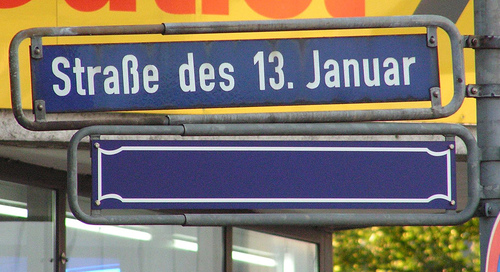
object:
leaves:
[367, 230, 393, 245]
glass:
[0, 174, 57, 271]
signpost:
[7, 22, 483, 244]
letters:
[393, 52, 416, 90]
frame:
[66, 121, 480, 224]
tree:
[329, 217, 483, 272]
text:
[52, 53, 161, 97]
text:
[52, 50, 415, 97]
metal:
[65, 125, 80, 217]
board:
[93, 139, 456, 211]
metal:
[308, 210, 344, 226]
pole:
[470, 2, 499, 269]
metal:
[41, 47, 108, 52]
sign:
[27, 32, 429, 103]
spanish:
[34, 50, 161, 94]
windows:
[0, 176, 321, 272]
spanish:
[51, 50, 416, 97]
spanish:
[244, 50, 416, 91]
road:
[57, 116, 116, 224]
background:
[316, 223, 474, 269]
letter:
[215, 52, 235, 97]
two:
[97, 140, 452, 202]